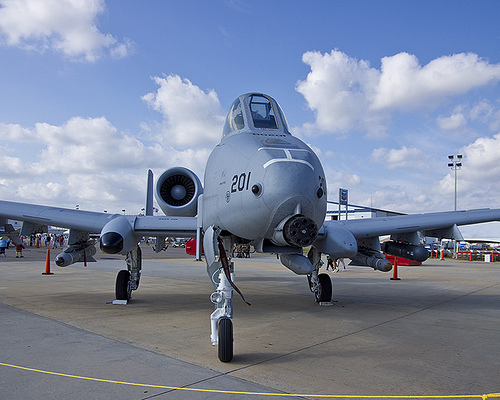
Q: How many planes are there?
A: One.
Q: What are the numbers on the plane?
A: 201.